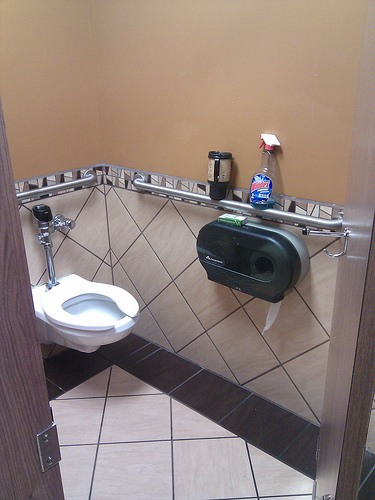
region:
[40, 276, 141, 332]
WHITE TOILET SEAT DOWN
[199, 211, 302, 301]
TOILET TISSUE WALL DISPENSER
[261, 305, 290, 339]
PART OF WHITE TOILET TISSUE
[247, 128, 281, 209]
BOTTLE OF SPRAY CLEANER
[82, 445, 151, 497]
PART OF SQUARE FLOOR TILES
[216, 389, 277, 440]
PART OF BLACK EDGE T ILE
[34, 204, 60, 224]
PUSH BUTTON FOR FLUSH TOILET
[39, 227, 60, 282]
WATER PIPE FOR TOILET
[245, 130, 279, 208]
bottle of blue Windex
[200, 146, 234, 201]
travel mug resting on the hand rail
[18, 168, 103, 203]
stainless steel hand rail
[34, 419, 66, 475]
silver metal door hinge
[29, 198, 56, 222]
automatic flushing device on the toilet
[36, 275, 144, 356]
white toilet attached to the wall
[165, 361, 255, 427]
black tile on the floor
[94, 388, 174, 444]
white tile on the floor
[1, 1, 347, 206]
the walls are tan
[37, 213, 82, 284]
pipes connected to the toilet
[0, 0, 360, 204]
solid tan covering on upper walls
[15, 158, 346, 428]
tiles with border on lower part of wall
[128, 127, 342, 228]
travel mug and cleaner on grab bar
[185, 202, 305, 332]
black and silver cover for hanging toilet paper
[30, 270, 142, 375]
toilet seat over bowl of elevated toilet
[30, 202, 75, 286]
button, sensor and plumbing against wall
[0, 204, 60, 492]
hinge along edge of wood door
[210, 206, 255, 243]
green packet left on top of toilet-paper holder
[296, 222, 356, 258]
attached hook and wall protector on door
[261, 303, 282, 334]
Toilet paper out of a dispenser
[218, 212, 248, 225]
Pack of cigarettes on a toilet paper dispenser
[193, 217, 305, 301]
Toilet paper dispenser on the wall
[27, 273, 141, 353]
Toilet in the bathroom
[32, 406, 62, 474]
Metal hinge on a bathroom wall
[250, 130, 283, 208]
Glass cleaner in a bathroom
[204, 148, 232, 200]
Coffee cup on a metal railing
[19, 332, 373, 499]
Tile on a bathroom floor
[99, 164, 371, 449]
Tile on a bathroom wall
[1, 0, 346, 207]
Tan colored bathroom wall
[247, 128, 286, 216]
windex bottle on handicap rail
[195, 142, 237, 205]
coffee cup on handicap rail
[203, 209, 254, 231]
green and white carton on toilet paper holder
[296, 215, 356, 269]
coat rack on bathroom stall door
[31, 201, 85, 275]
silver water pipe for toilet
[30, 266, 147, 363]
white toilet in bathroom stall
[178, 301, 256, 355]
brown tile on bathroom wall